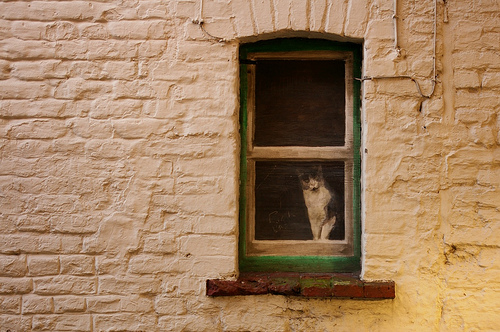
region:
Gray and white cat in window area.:
[298, 167, 341, 239]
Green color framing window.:
[238, 43, 356, 268]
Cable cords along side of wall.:
[366, 6, 442, 99]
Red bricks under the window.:
[206, 277, 394, 298]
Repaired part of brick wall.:
[99, 158, 166, 260]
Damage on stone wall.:
[287, 302, 327, 328]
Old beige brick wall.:
[13, 45, 118, 106]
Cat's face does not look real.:
[299, 166, 324, 191]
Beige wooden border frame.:
[247, 58, 352, 255]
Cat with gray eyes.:
[300, 166, 341, 238]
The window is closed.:
[242, 29, 381, 264]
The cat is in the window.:
[251, 147, 363, 241]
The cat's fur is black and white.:
[306, 187, 342, 223]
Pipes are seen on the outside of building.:
[376, 2, 453, 106]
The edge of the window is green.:
[239, 242, 374, 277]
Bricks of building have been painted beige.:
[106, 55, 183, 120]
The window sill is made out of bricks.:
[203, 269, 405, 306]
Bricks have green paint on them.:
[264, 266, 357, 299]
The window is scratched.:
[260, 198, 303, 237]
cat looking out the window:
[288, 171, 338, 235]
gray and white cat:
[295, 163, 340, 239]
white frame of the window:
[241, 52, 352, 258]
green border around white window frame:
[240, 46, 361, 267]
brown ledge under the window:
[208, 273, 393, 304]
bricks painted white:
[5, 7, 494, 326]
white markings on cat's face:
[305, 178, 318, 189]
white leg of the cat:
[316, 220, 334, 241]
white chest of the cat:
[303, 193, 328, 218]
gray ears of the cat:
[293, 159, 323, 178]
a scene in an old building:
[6, 7, 481, 318]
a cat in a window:
[282, 165, 374, 255]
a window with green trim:
[190, 30, 382, 288]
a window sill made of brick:
[202, 263, 446, 328]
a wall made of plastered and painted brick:
[69, 105, 185, 233]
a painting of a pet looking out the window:
[231, 107, 393, 283]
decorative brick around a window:
[222, 5, 392, 53]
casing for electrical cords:
[371, 60, 461, 107]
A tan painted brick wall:
[1, 0, 498, 330]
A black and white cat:
[292, 162, 345, 241]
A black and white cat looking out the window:
[291, 162, 344, 241]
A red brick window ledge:
[205, 269, 397, 300]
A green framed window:
[238, 35, 364, 275]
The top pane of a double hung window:
[241, 47, 356, 159]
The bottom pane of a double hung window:
[241, 156, 358, 260]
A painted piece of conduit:
[390, 1, 400, 53]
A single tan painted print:
[32, 273, 101, 297]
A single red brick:
[361, 279, 396, 301]